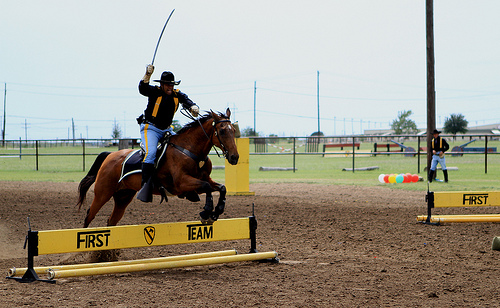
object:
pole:
[36, 142, 39, 170]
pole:
[0, 135, 141, 172]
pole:
[426, 0, 436, 179]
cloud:
[0, 0, 500, 142]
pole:
[253, 81, 256, 145]